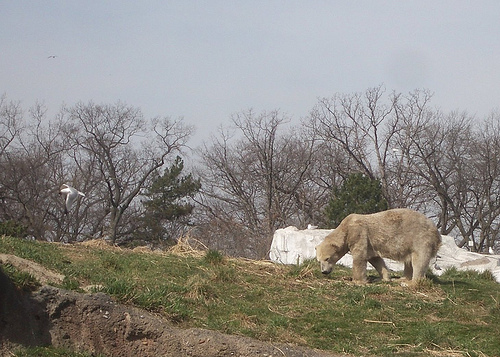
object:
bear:
[315, 207, 446, 287]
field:
[0, 235, 500, 356]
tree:
[132, 152, 204, 248]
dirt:
[0, 284, 329, 356]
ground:
[0, 233, 500, 356]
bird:
[58, 181, 86, 200]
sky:
[0, 1, 500, 215]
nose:
[321, 265, 328, 272]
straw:
[188, 235, 207, 253]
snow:
[268, 222, 500, 282]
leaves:
[185, 182, 192, 187]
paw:
[351, 276, 368, 286]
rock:
[46, 294, 76, 319]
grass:
[0, 235, 500, 356]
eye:
[323, 254, 331, 262]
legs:
[352, 238, 373, 283]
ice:
[268, 224, 335, 265]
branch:
[66, 151, 104, 192]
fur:
[368, 217, 386, 226]